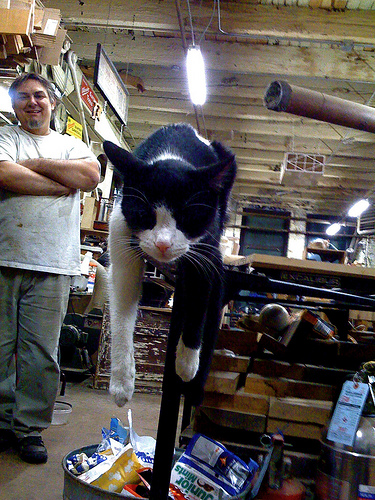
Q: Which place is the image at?
A: It is at the store.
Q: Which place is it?
A: It is a store.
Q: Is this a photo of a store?
A: Yes, it is showing a store.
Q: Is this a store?
A: Yes, it is a store.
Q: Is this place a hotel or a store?
A: It is a store.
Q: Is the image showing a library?
A: No, the picture is showing a store.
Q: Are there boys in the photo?
A: No, there are no boys.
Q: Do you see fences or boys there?
A: No, there are no boys or fences.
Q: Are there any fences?
A: No, there are no fences.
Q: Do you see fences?
A: No, there are no fences.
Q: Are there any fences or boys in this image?
A: No, there are no fences or boys.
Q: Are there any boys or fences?
A: No, there are no fences or boys.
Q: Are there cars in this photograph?
A: No, there are no cars.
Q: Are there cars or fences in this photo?
A: No, there are no cars or fences.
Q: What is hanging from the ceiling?
A: The sign is hanging from the ceiling.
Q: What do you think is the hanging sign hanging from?
A: The sign is hanging from the ceiling.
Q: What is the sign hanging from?
A: The sign is hanging from the ceiling.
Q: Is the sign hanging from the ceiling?
A: Yes, the sign is hanging from the ceiling.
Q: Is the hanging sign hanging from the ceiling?
A: Yes, the sign is hanging from the ceiling.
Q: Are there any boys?
A: No, there are no boys.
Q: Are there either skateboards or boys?
A: No, there are no boys or skateboards.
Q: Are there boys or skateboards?
A: No, there are no boys or skateboards.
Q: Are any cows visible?
A: No, there are no cows.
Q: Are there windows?
A: Yes, there is a window.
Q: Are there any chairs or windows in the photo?
A: Yes, there is a window.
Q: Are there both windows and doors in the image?
A: No, there is a window but no doors.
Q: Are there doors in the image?
A: No, there are no doors.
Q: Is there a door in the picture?
A: No, there are no doors.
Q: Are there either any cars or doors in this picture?
A: No, there are no doors or cars.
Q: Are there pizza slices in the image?
A: No, there are no pizza slices.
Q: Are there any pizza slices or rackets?
A: No, there are no pizza slices or rackets.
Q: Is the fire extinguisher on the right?
A: Yes, the fire extinguisher is on the right of the image.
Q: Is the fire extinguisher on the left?
A: No, the fire extinguisher is on the right of the image.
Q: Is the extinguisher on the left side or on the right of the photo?
A: The extinguisher is on the right of the image.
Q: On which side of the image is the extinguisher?
A: The extinguisher is on the right of the image.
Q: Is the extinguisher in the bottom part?
A: Yes, the extinguisher is in the bottom of the image.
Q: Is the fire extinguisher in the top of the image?
A: No, the fire extinguisher is in the bottom of the image.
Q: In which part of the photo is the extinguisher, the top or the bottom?
A: The extinguisher is in the bottom of the image.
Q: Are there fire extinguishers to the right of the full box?
A: Yes, there is a fire extinguisher to the right of the box.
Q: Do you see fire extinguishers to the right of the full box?
A: Yes, there is a fire extinguisher to the right of the box.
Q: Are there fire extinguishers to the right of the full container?
A: Yes, there is a fire extinguisher to the right of the box.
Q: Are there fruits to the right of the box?
A: No, there is a fire extinguisher to the right of the box.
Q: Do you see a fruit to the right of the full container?
A: No, there is a fire extinguisher to the right of the box.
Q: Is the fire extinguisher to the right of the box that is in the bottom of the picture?
A: Yes, the fire extinguisher is to the right of the box.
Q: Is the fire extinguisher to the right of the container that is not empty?
A: Yes, the fire extinguisher is to the right of the box.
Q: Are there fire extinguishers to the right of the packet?
A: Yes, there is a fire extinguisher to the right of the packet.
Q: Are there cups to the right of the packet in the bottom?
A: No, there is a fire extinguisher to the right of the packet.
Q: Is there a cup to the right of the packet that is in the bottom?
A: No, there is a fire extinguisher to the right of the packet.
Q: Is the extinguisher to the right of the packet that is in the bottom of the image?
A: Yes, the extinguisher is to the right of the packet.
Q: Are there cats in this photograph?
A: Yes, there is a cat.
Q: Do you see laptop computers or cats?
A: Yes, there is a cat.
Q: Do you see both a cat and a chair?
A: No, there is a cat but no chairs.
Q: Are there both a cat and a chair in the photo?
A: No, there is a cat but no chairs.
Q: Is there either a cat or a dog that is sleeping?
A: Yes, the cat is sleeping.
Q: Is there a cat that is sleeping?
A: Yes, there is a cat that is sleeping.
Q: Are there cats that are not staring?
A: Yes, there is a cat that is sleeping.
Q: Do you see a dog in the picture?
A: No, there are no dogs.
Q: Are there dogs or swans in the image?
A: No, there are no dogs or swans.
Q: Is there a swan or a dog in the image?
A: No, there are no dogs or swans.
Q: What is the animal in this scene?
A: The animal is a cat.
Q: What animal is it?
A: The animal is a cat.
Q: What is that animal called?
A: This is a cat.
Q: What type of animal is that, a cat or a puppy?
A: This is a cat.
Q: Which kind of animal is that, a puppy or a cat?
A: This is a cat.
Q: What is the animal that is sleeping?
A: The animal is a cat.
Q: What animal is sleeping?
A: The animal is a cat.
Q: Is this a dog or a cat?
A: This is a cat.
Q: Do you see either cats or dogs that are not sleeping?
A: No, there is a cat but it is sleeping.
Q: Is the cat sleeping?
A: Yes, the cat is sleeping.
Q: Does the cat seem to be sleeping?
A: Yes, the cat is sleeping.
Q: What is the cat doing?
A: The cat is sleeping.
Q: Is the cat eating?
A: No, the cat is sleeping.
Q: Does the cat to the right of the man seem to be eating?
A: No, the cat is sleeping.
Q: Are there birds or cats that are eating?
A: No, there is a cat but it is sleeping.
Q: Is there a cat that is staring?
A: No, there is a cat but it is sleeping.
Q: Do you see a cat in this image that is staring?
A: No, there is a cat but it is sleeping.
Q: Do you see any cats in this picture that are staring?
A: No, there is a cat but it is sleeping.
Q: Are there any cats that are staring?
A: No, there is a cat but it is sleeping.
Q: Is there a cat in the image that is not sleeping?
A: No, there is a cat but it is sleeping.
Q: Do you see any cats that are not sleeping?
A: No, there is a cat but it is sleeping.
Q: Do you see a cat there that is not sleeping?
A: No, there is a cat but it is sleeping.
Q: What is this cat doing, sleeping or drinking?
A: The cat is sleeping.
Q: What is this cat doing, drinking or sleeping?
A: The cat is sleeping.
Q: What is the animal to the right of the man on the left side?
A: The animal is a cat.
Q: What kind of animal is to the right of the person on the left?
A: The animal is a cat.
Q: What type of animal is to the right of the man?
A: The animal is a cat.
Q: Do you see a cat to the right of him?
A: Yes, there is a cat to the right of the man.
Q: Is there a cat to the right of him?
A: Yes, there is a cat to the right of the man.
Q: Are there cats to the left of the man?
A: No, the cat is to the right of the man.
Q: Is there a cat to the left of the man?
A: No, the cat is to the right of the man.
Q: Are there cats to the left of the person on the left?
A: No, the cat is to the right of the man.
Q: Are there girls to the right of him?
A: No, there is a cat to the right of the man.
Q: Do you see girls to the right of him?
A: No, there is a cat to the right of the man.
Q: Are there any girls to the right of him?
A: No, there is a cat to the right of the man.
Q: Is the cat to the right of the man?
A: Yes, the cat is to the right of the man.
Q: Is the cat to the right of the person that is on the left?
A: Yes, the cat is to the right of the man.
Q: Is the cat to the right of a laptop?
A: No, the cat is to the right of the man.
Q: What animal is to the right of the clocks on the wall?
A: The animal is a cat.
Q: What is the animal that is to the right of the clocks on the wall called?
A: The animal is a cat.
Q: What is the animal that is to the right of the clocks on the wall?
A: The animal is a cat.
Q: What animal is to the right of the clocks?
A: The animal is a cat.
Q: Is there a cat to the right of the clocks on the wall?
A: Yes, there is a cat to the right of the clocks.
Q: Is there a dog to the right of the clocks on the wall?
A: No, there is a cat to the right of the clocks.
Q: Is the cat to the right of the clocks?
A: Yes, the cat is to the right of the clocks.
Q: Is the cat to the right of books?
A: No, the cat is to the right of the clocks.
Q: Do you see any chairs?
A: No, there are no chairs.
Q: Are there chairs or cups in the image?
A: No, there are no chairs or cups.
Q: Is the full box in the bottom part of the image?
A: Yes, the box is in the bottom of the image.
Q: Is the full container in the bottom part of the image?
A: Yes, the box is in the bottom of the image.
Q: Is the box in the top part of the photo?
A: No, the box is in the bottom of the image.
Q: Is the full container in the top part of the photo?
A: No, the box is in the bottom of the image.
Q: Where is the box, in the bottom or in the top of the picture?
A: The box is in the bottom of the image.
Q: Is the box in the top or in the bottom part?
A: The box is in the bottom of the image.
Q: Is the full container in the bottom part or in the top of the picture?
A: The box is in the bottom of the image.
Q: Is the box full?
A: Yes, the box is full.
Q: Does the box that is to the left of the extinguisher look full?
A: Yes, the box is full.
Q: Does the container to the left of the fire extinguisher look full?
A: Yes, the box is full.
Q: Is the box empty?
A: No, the box is full.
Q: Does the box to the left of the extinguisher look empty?
A: No, the box is full.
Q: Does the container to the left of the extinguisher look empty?
A: No, the box is full.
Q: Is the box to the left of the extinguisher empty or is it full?
A: The box is full.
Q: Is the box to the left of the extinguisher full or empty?
A: The box is full.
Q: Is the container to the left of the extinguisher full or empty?
A: The box is full.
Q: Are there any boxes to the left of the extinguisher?
A: Yes, there is a box to the left of the extinguisher.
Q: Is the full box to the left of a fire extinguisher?
A: Yes, the box is to the left of a fire extinguisher.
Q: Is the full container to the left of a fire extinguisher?
A: Yes, the box is to the left of a fire extinguisher.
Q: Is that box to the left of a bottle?
A: No, the box is to the left of a fire extinguisher.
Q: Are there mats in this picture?
A: No, there are no mats.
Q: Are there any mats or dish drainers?
A: No, there are no mats or dish drainers.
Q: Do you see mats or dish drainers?
A: No, there are no mats or dish drainers.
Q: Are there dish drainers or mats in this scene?
A: No, there are no mats or dish drainers.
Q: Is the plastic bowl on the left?
A: Yes, the bowl is on the left of the image.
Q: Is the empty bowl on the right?
A: No, the bowl is on the left of the image.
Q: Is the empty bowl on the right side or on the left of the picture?
A: The bowl is on the left of the image.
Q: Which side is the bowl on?
A: The bowl is on the left of the image.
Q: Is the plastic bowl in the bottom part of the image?
A: Yes, the bowl is in the bottom of the image.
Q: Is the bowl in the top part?
A: No, the bowl is in the bottom of the image.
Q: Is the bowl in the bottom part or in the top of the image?
A: The bowl is in the bottom of the image.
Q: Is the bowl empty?
A: Yes, the bowl is empty.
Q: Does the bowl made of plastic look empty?
A: Yes, the bowl is empty.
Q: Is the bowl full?
A: No, the bowl is empty.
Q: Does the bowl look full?
A: No, the bowl is empty.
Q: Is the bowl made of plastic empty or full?
A: The bowl is empty.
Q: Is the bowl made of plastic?
A: Yes, the bowl is made of plastic.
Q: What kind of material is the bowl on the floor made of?
A: The bowl is made of plastic.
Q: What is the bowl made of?
A: The bowl is made of plastic.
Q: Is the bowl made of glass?
A: No, the bowl is made of plastic.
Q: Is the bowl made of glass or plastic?
A: The bowl is made of plastic.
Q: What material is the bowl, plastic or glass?
A: The bowl is made of plastic.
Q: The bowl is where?
A: The bowl is on the floor.